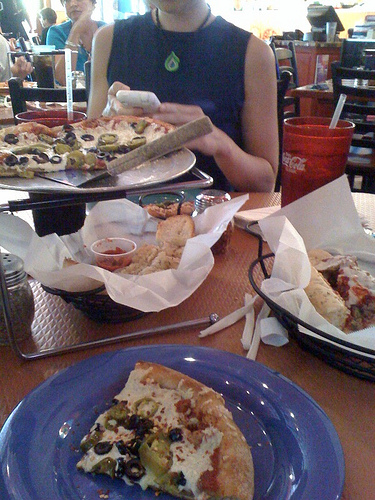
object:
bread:
[155, 212, 195, 252]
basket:
[39, 281, 153, 323]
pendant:
[164, 50, 180, 72]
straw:
[328, 93, 348, 127]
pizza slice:
[302, 247, 373, 329]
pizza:
[0, 111, 178, 175]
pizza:
[78, 357, 255, 500]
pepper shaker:
[0, 247, 35, 348]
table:
[0, 185, 374, 497]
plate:
[0, 341, 346, 500]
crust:
[134, 357, 192, 388]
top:
[108, 17, 254, 188]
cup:
[279, 115, 352, 211]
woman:
[46, 0, 108, 85]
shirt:
[45, 19, 106, 72]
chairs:
[268, 39, 328, 196]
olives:
[112, 452, 126, 483]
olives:
[135, 420, 146, 438]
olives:
[94, 440, 110, 455]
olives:
[168, 426, 182, 440]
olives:
[117, 439, 128, 454]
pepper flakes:
[190, 189, 232, 258]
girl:
[82, 0, 283, 198]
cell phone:
[115, 89, 162, 115]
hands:
[148, 102, 215, 155]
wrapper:
[198, 291, 259, 338]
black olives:
[125, 456, 146, 481]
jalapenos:
[140, 428, 172, 476]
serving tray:
[2, 143, 197, 194]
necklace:
[151, 4, 211, 71]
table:
[292, 71, 374, 114]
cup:
[32, 50, 57, 88]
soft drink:
[31, 53, 55, 86]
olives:
[50, 153, 62, 164]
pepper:
[211, 221, 232, 254]